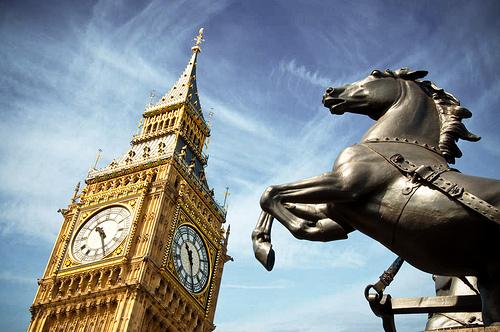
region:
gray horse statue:
[237, 49, 469, 329]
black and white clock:
[82, 199, 139, 269]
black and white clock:
[163, 220, 205, 290]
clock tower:
[87, 22, 230, 322]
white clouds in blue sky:
[22, 15, 71, 69]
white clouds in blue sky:
[64, 41, 106, 87]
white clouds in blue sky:
[9, 100, 47, 151]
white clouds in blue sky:
[257, 272, 321, 316]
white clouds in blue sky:
[232, 115, 272, 162]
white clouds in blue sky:
[264, 48, 294, 100]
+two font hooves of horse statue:
[158, 210, 353, 320]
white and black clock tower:
[125, 228, 213, 315]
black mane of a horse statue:
[370, 44, 477, 189]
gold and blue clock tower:
[54, 64, 224, 330]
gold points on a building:
[30, 149, 245, 191]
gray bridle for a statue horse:
[301, 140, 486, 300]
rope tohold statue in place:
[335, 247, 417, 307]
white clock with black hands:
[56, 206, 136, 272]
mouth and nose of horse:
[271, 72, 366, 152]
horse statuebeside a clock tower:
[20, 59, 453, 314]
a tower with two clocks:
[20, 15, 239, 329]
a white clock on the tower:
[162, 215, 217, 300]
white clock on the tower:
[63, 198, 136, 266]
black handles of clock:
[92, 216, 107, 257]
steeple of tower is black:
[142, 19, 224, 124]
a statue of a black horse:
[241, 45, 499, 329]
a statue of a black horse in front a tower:
[127, 21, 494, 325]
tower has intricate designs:
[31, 21, 238, 329]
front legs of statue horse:
[241, 153, 351, 285]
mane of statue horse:
[397, 56, 487, 182]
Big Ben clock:
[41, 23, 220, 329]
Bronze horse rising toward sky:
[250, 60, 498, 316]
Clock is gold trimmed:
[34, 162, 223, 330]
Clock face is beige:
[180, 239, 203, 275]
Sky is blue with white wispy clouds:
[13, 17, 133, 127]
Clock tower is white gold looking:
[94, 22, 224, 188]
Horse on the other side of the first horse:
[421, 276, 482, 329]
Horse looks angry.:
[317, 65, 472, 136]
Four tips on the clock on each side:
[178, 142, 189, 167]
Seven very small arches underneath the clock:
[42, 265, 129, 297]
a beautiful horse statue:
[251, 47, 498, 322]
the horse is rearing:
[247, 27, 489, 299]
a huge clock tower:
[6, 8, 234, 328]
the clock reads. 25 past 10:
[161, 207, 225, 294]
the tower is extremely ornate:
[33, 8, 230, 326]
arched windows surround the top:
[143, 108, 213, 158]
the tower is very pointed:
[119, 14, 254, 163]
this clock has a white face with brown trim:
[68, 200, 135, 269]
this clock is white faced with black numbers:
[165, 213, 216, 298]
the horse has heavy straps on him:
[371, 124, 498, 244]